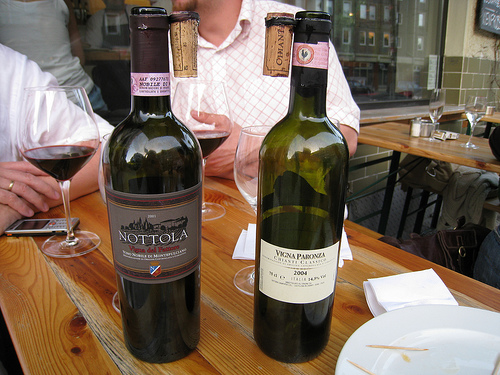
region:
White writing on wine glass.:
[120, 221, 211, 261]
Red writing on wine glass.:
[120, 235, 192, 260]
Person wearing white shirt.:
[3, 72, 28, 154]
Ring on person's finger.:
[6, 169, 40, 214]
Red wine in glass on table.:
[22, 125, 106, 211]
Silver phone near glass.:
[18, 204, 70, 252]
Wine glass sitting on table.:
[189, 108, 232, 245]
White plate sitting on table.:
[361, 288, 418, 366]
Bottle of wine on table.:
[243, 215, 317, 368]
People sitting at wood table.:
[83, 279, 254, 370]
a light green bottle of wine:
[247, 22, 371, 373]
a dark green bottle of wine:
[91, 77, 200, 358]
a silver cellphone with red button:
[21, 200, 63, 231]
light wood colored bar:
[54, 321, 104, 339]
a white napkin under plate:
[362, 267, 456, 316]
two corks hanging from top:
[160, 11, 334, 94]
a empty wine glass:
[225, 122, 281, 257]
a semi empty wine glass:
[21, 80, 84, 254]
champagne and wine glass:
[421, 87, 482, 148]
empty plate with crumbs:
[370, 339, 430, 368]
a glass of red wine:
[11, 77, 108, 264]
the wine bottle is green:
[234, 5, 361, 366]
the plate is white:
[333, 294, 498, 374]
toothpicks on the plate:
[331, 308, 499, 373]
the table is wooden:
[0, 162, 497, 373]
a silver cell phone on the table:
[2, 210, 84, 242]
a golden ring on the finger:
[1, 156, 60, 218]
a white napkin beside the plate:
[336, 267, 498, 373]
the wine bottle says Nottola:
[96, 5, 208, 363]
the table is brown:
[1, 169, 499, 374]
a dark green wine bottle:
[252, 10, 350, 364]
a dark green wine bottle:
[100, 5, 208, 365]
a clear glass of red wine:
[18, 82, 100, 258]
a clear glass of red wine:
[171, 76, 230, 222]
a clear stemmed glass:
[231, 123, 278, 302]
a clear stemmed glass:
[426, 85, 446, 137]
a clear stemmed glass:
[458, 91, 488, 151]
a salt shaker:
[408, 116, 421, 138]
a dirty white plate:
[332, 304, 494, 372]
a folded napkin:
[360, 266, 460, 313]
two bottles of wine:
[106, 5, 345, 365]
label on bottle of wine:
[103, 185, 210, 283]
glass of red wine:
[17, 79, 102, 261]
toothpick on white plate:
[359, 337, 434, 354]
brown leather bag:
[391, 223, 491, 265]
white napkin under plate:
[359, 268, 466, 325]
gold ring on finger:
[6, 173, 18, 192]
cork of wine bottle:
[262, 5, 292, 83]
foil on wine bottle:
[126, 13, 170, 75]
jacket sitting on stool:
[453, 163, 492, 225]